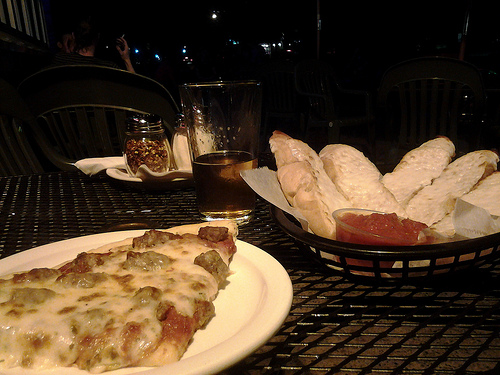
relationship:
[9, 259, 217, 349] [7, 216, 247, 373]
sauce on pizza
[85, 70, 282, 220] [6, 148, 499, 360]
condiments on table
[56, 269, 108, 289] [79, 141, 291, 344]
topping on pizza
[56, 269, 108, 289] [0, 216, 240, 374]
topping on pizza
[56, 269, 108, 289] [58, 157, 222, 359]
topping on pizza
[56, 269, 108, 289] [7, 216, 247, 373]
topping on pizza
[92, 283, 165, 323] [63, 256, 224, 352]
topping on pizza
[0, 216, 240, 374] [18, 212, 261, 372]
pizza on pizza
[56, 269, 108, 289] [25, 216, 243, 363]
topping on pizza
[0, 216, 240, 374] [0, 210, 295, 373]
pizza on plate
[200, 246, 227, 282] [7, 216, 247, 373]
sausage on pizza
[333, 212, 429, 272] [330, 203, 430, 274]
sauce in cup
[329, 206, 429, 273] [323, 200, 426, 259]
sauce in cup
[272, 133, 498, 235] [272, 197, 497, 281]
bread in basket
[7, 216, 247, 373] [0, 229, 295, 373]
pizza on plate